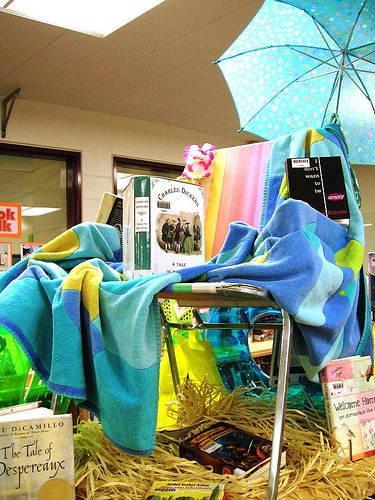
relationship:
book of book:
[0, 401, 75, 498] [0, 366, 104, 498]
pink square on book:
[318, 358, 357, 384] [320, 354, 374, 464]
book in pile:
[178, 420, 287, 480] [149, 396, 297, 496]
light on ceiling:
[0, 0, 167, 38] [1, 3, 267, 143]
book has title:
[0, 395, 82, 498] [1, 437, 67, 486]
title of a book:
[11, 432, 43, 498] [22, 416, 41, 462]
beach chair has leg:
[155, 283, 330, 498] [263, 306, 294, 498]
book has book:
[319, 354, 374, 463] [320, 354, 374, 464]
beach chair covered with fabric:
[156, 281, 294, 498] [139, 267, 295, 316]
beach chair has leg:
[156, 281, 294, 498] [261, 306, 291, 498]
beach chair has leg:
[156, 281, 294, 498] [155, 304, 182, 397]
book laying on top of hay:
[174, 420, 291, 480] [72, 371, 375, 499]